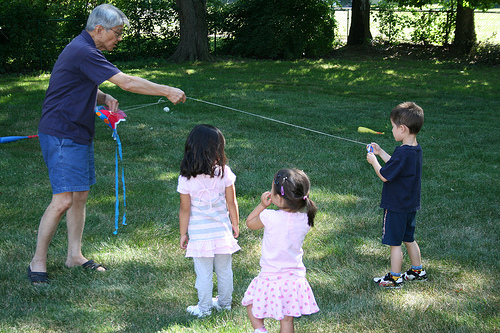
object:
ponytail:
[303, 194, 318, 227]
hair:
[273, 166, 318, 229]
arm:
[86, 51, 164, 97]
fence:
[331, 7, 500, 50]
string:
[184, 97, 373, 149]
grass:
[0, 40, 498, 331]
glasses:
[108, 28, 123, 38]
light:
[185, 68, 197, 75]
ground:
[0, 51, 500, 333]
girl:
[238, 164, 323, 331]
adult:
[26, 2, 188, 289]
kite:
[91, 92, 376, 237]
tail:
[108, 127, 130, 239]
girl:
[174, 120, 243, 319]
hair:
[179, 122, 226, 181]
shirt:
[174, 165, 243, 259]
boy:
[365, 100, 429, 290]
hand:
[166, 86, 187, 106]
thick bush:
[212, 0, 337, 62]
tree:
[346, 0, 375, 48]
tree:
[168, 0, 216, 64]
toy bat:
[356, 125, 385, 135]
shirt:
[237, 269, 322, 319]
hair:
[84, 2, 131, 34]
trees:
[449, 0, 479, 54]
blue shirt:
[377, 143, 422, 213]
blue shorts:
[380, 207, 418, 247]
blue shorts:
[33, 129, 97, 195]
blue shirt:
[36, 28, 122, 146]